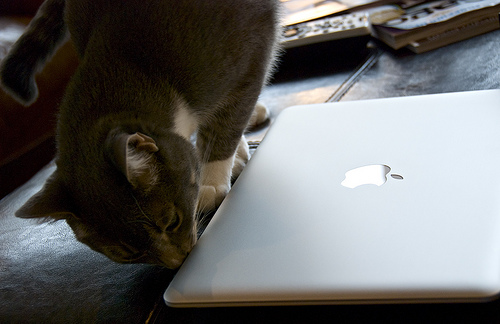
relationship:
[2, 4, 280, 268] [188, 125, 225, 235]
cat has whiskers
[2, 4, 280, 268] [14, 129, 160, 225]
cat has ears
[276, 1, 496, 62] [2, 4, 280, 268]
magazines behind cat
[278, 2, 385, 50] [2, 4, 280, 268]
remote control behind cat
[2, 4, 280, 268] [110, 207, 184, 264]
cat has eyes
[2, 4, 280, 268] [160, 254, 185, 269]
cat has a nose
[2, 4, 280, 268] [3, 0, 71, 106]
cat has a tail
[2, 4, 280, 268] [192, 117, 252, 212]
cat has paws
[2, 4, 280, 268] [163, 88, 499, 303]
cat sniffing laptop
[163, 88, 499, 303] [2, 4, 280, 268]
laptop next to cat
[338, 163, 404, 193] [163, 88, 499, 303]
logo on laptop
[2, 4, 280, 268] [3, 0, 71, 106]
cat has tail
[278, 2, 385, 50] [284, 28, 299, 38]
remote control has button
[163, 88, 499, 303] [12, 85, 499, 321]
laptop on desk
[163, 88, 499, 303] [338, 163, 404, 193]
computer has symbol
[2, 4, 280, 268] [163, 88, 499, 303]
cat smelling computer